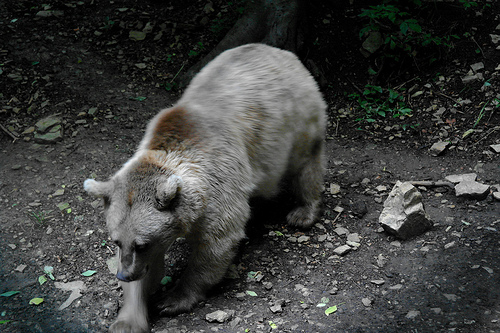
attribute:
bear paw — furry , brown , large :
[104, 304, 155, 331]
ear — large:
[137, 167, 212, 207]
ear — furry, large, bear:
[66, 177, 122, 193]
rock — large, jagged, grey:
[377, 180, 427, 237]